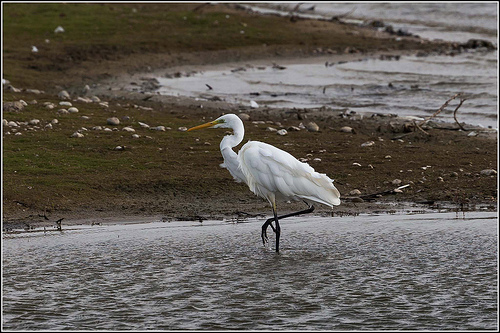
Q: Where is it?
A: This is at the shore.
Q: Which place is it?
A: It is a shore.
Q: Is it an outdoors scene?
A: Yes, it is outdoors.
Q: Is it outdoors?
A: Yes, it is outdoors.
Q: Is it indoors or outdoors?
A: It is outdoors.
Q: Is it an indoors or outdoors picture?
A: It is outdoors.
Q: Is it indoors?
A: No, it is outdoors.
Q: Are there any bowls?
A: No, there are no bowls.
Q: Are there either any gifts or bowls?
A: No, there are no bowls or gifts.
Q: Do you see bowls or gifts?
A: No, there are no bowls or gifts.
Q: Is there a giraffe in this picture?
A: No, there are no giraffes.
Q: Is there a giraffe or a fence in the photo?
A: No, there are no giraffes or fences.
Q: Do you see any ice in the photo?
A: Yes, there is ice.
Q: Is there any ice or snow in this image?
A: Yes, there is ice.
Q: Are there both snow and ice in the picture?
A: No, there is ice but no snow.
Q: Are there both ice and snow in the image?
A: No, there is ice but no snow.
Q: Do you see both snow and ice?
A: No, there is ice but no snow.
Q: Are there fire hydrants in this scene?
A: No, there are no fire hydrants.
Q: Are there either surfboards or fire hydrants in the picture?
A: No, there are no fire hydrants or surfboards.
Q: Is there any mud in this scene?
A: Yes, there is mud.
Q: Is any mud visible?
A: Yes, there is mud.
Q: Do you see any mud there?
A: Yes, there is mud.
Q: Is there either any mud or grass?
A: Yes, there is mud.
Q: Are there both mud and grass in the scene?
A: Yes, there are both mud and grass.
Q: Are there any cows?
A: No, there are no cows.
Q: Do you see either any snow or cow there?
A: No, there are no cows or snow.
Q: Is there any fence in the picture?
A: No, there are no fences.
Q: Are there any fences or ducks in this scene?
A: No, there are no fences or ducks.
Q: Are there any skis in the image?
A: No, there are no skis.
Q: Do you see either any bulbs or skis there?
A: No, there are no skis or bulbs.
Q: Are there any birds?
A: Yes, there is a bird.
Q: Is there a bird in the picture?
A: Yes, there is a bird.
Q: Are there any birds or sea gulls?
A: Yes, there is a bird.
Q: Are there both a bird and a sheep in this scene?
A: No, there is a bird but no sheep.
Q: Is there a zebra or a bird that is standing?
A: Yes, the bird is standing.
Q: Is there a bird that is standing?
A: Yes, there is a bird that is standing.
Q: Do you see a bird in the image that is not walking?
A: Yes, there is a bird that is standing .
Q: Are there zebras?
A: No, there are no zebras.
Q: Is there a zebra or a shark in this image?
A: No, there are no zebras or sharks.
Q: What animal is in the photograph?
A: The animal is a bird.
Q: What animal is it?
A: The animal is a bird.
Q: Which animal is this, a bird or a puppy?
A: This is a bird.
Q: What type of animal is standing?
A: The animal is a bird.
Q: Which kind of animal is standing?
A: The animal is a bird.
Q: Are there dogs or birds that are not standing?
A: No, there is a bird but it is standing.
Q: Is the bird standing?
A: Yes, the bird is standing.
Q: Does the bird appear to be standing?
A: Yes, the bird is standing.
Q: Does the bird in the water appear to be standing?
A: Yes, the bird is standing.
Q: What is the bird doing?
A: The bird is standing.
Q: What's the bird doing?
A: The bird is standing.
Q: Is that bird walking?
A: No, the bird is standing.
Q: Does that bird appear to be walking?
A: No, the bird is standing.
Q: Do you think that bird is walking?
A: No, the bird is standing.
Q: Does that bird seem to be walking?
A: No, the bird is standing.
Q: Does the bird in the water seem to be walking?
A: No, the bird is standing.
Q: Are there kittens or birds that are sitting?
A: No, there is a bird but it is standing.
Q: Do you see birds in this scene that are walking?
A: No, there is a bird but it is standing.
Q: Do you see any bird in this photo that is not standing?
A: No, there is a bird but it is standing.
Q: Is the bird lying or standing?
A: The bird is standing.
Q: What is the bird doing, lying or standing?
A: The bird is standing.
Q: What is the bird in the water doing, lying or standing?
A: The bird is standing.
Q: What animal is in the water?
A: The bird is in the water.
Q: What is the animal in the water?
A: The animal is a bird.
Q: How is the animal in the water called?
A: The animal is a bird.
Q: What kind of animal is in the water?
A: The animal is a bird.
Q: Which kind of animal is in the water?
A: The animal is a bird.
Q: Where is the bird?
A: The bird is in the water.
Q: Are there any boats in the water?
A: No, there is a bird in the water.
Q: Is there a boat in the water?
A: No, there is a bird in the water.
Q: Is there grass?
A: Yes, there is grass.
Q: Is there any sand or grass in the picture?
A: Yes, there is grass.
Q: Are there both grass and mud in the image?
A: Yes, there are both grass and mud.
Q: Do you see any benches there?
A: No, there are no benches.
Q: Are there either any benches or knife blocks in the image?
A: No, there are no benches or knife blocks.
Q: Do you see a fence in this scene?
A: No, there are no fences.